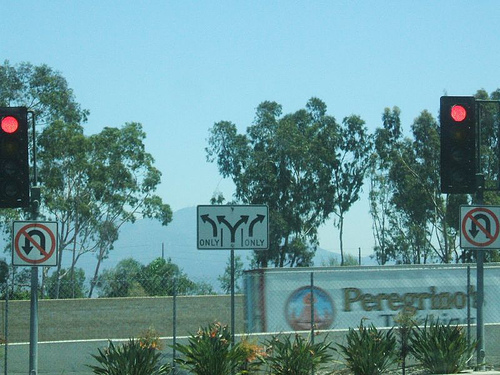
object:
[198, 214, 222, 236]
turn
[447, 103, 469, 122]
light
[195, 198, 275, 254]
sign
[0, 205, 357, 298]
mountains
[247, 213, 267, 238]
arrow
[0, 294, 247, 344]
wall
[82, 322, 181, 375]
plant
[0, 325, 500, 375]
road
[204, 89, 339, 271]
tree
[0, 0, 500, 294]
sky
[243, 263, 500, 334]
barrier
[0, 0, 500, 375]
photo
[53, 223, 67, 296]
truck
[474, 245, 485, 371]
pole